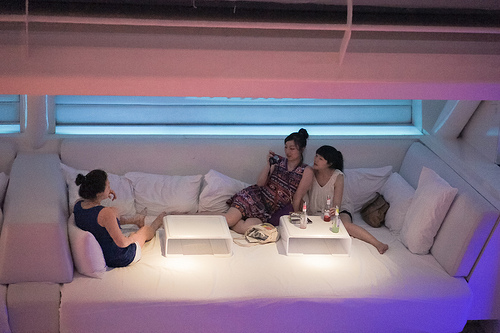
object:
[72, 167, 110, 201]
hair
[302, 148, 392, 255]
woman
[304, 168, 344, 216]
dress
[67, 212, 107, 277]
pillow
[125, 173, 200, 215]
pillow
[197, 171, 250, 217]
pillow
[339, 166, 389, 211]
pillow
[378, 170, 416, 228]
pillow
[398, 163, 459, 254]
pillow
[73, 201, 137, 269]
dress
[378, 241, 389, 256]
foot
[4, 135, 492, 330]
couch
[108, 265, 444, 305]
front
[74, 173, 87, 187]
bun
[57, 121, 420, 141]
reflection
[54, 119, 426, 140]
sill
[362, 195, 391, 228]
purse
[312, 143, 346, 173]
hair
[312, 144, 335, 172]
head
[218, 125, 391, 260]
eachother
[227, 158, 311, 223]
dress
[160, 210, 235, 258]
trays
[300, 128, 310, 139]
ponytail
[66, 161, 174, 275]
woman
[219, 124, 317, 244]
woman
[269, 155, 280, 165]
camera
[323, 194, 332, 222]
bottle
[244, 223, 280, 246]
bag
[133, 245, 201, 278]
light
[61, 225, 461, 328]
sheet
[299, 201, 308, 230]
bottle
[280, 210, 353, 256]
table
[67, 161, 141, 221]
pillow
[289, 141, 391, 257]
girl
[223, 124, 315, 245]
girl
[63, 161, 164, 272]
girl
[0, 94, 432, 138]
windows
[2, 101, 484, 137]
wall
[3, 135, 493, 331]
furniture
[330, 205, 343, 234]
bottle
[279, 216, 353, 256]
tray